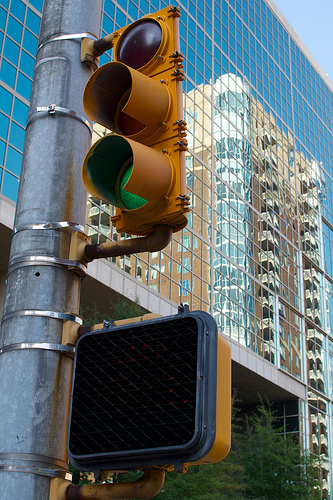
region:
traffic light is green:
[92, 19, 233, 222]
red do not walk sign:
[59, 310, 198, 476]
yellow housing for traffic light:
[106, 47, 186, 237]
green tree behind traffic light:
[152, 405, 330, 497]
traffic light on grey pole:
[10, 28, 84, 315]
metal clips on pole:
[39, 27, 92, 222]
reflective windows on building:
[201, 54, 318, 338]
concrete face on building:
[93, 260, 302, 397]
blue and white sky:
[269, 0, 332, 58]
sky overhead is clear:
[287, 0, 331, 50]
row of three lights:
[75, 18, 212, 233]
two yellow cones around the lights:
[65, 56, 190, 223]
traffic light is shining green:
[83, 8, 214, 252]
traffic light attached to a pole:
[14, 1, 225, 283]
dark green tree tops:
[116, 386, 327, 498]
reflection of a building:
[73, 64, 332, 393]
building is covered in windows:
[0, 0, 332, 494]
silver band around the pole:
[2, 305, 79, 331]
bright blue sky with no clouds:
[271, 1, 331, 78]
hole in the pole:
[34, 269, 41, 278]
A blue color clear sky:
[297, 4, 325, 29]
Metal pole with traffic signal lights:
[0, 9, 206, 498]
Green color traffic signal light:
[74, 133, 175, 218]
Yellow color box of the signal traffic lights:
[83, 4, 200, 260]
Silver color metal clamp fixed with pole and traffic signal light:
[2, 215, 88, 359]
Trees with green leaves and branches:
[239, 416, 294, 497]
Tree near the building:
[230, 407, 306, 499]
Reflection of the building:
[186, 67, 331, 360]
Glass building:
[224, 5, 307, 65]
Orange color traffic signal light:
[81, 75, 165, 129]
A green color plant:
[241, 401, 284, 497]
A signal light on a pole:
[85, 25, 185, 273]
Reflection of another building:
[193, 63, 326, 354]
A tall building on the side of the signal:
[198, 0, 324, 221]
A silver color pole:
[10, 0, 79, 227]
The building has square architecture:
[185, 5, 273, 81]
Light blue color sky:
[273, 0, 328, 86]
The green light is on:
[71, 128, 207, 241]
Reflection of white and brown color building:
[169, 157, 328, 303]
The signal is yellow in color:
[74, 11, 208, 233]